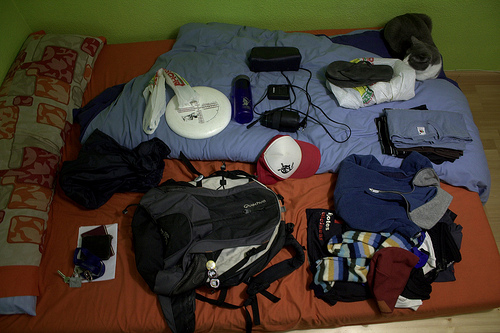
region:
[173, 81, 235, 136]
white frisbee lying on blanket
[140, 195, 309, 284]
grey and black book bag on bed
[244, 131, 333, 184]
red and white baseball cap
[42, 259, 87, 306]
keys on orange blanket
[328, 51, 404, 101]
black sandals on bed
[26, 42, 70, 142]
orange patterned right pillow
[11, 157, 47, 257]
orange patterned left pillow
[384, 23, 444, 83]
grey and white cat at edge of bed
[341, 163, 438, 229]
blue and grey shirt on bed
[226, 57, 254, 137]
blue water bottle on bed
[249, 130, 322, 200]
White and red hat next to backpack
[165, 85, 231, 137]
White frisbee next to blue water bottle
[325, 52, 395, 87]
Sandals on top of white plastic bag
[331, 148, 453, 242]
Blue jacket near hat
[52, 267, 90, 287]
Keys on top of bed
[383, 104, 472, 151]
Blue shirt near blue jacket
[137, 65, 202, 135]
Plastic bag on top of frisbee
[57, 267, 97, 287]
Keys near black backpack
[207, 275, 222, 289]
Round pin on backpack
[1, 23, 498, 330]
Orange sheet on bed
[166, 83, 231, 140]
a round white frisbee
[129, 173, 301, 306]
a black and white backpack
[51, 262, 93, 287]
a set of keys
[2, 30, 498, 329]
a bed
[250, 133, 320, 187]
a red and white hat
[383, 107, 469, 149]
a folded blue t-shirt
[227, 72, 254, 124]
a blue plastic water bottle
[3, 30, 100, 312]
a bed length pillow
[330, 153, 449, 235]
a blue pull over jacket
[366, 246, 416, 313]
a pair of red socks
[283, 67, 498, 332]
The floor is made of wood.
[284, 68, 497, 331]
The floor is light brown.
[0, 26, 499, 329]
The bed is red.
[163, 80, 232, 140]
A frisbee.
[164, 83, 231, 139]
The frisbee is made of plastic.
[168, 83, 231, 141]
The frisbee is white.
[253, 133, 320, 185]
A hat.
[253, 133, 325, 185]
The hat is red and white.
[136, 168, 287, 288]
A backpack.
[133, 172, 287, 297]
The backpack is gray, white and black.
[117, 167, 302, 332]
a black gray and white backpack on a bed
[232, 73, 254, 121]
a blue bottle on a bed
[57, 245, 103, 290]
a set of keys on a bed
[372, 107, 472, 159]
a pile of folded t shirts on a bed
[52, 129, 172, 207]
a black umbrella on a bed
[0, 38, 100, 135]
a pillow on a bed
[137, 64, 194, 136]
a plastic white grocery store bag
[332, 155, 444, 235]
a fleece jacket folded on a bed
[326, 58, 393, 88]
a pair of black flip flops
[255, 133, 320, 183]
a red and white baseball cap